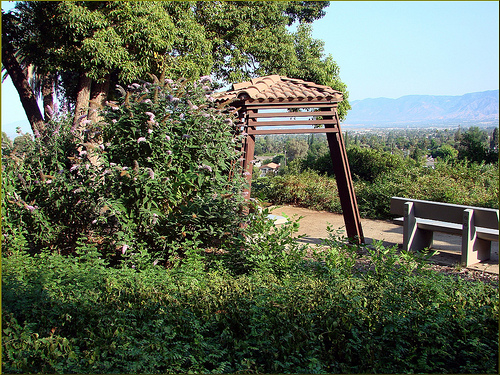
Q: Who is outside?
A: There is no one outside.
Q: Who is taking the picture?
A: A photographer.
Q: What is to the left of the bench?
A: A path.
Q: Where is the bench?
A: On the sidewalk.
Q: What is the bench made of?
A: Cement.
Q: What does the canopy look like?
A: Brown.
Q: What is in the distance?
A: Mountains.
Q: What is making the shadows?
A: The trees.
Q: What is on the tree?
A: Purple flowers.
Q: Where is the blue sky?
A: Above land.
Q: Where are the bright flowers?
A: Next to the structure.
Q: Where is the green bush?
A: Next to the structure.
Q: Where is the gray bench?
A: On the ground.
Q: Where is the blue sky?
A: Above land.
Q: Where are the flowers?
A: Next to the structure.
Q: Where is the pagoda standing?
A: On the sidewalk.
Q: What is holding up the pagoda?
A: Support legs.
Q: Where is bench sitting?
A: On the sidewalk.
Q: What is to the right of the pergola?
A: Bench.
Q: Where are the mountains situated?
A: Background.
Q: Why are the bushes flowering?
A: Springtime.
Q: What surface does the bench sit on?
A: Walkway.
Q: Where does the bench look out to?
A: Mountains.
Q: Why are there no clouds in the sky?
A: Clear.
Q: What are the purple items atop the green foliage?
A: Flowers.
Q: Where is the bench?
A: On the path.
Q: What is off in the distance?
A: Mountains.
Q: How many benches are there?
A: One.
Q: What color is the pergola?
A: Brown.